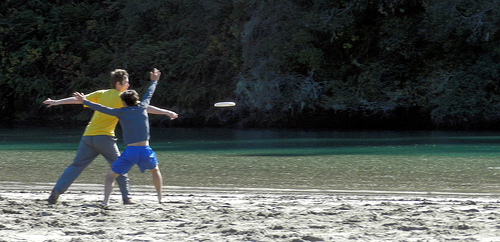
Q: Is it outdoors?
A: Yes, it is outdoors.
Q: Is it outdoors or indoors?
A: It is outdoors.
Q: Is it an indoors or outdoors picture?
A: It is outdoors.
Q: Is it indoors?
A: No, it is outdoors.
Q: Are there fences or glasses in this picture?
A: No, there are no fences or glasses.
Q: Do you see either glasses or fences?
A: No, there are no fences or glasses.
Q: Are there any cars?
A: No, there are no cars.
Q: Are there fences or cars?
A: No, there are no cars or fences.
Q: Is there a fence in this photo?
A: No, there are no fences.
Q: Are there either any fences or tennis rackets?
A: No, there are no fences or tennis rackets.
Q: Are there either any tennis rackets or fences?
A: No, there are no fences or tennis rackets.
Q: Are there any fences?
A: No, there are no fences.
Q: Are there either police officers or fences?
A: No, there are no fences or police officers.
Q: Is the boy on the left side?
A: Yes, the boy is on the left of the image.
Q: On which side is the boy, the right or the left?
A: The boy is on the left of the image.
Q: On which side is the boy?
A: The boy is on the left of the image.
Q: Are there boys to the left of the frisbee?
A: Yes, there is a boy to the left of the frisbee.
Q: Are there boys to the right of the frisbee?
A: No, the boy is to the left of the frisbee.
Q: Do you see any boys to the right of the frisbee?
A: No, the boy is to the left of the frisbee.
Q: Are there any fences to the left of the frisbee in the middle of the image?
A: No, there is a boy to the left of the frisbee.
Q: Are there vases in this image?
A: No, there are no vases.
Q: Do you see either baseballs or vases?
A: No, there are no vases or baseballs.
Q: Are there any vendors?
A: No, there are no vendors.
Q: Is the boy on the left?
A: Yes, the boy is on the left of the image.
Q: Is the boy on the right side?
A: No, the boy is on the left of the image.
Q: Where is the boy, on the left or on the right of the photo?
A: The boy is on the left of the image.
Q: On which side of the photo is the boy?
A: The boy is on the left of the image.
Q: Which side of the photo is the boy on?
A: The boy is on the left of the image.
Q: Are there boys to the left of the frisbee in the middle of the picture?
A: Yes, there is a boy to the left of the frisbee.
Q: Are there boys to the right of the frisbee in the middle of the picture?
A: No, the boy is to the left of the frisbee.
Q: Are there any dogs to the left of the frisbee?
A: No, there is a boy to the left of the frisbee.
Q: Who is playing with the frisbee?
A: The boy is playing with the frisbee.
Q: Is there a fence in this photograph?
A: No, there are no fences.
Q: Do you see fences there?
A: No, there are no fences.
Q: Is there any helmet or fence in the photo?
A: No, there are no fences or helmets.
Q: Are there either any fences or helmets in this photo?
A: No, there are no fences or helmets.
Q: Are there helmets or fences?
A: No, there are no fences or helmets.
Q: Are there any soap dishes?
A: No, there are no soap dishes.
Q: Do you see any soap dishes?
A: No, there are no soap dishes.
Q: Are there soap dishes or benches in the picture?
A: No, there are no soap dishes or benches.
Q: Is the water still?
A: Yes, the water is still.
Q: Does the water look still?
A: Yes, the water is still.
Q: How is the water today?
A: The water is still.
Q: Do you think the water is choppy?
A: No, the water is still.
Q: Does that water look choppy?
A: No, the water is still.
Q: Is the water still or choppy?
A: The water is still.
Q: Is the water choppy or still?
A: The water is still.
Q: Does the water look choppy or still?
A: The water is still.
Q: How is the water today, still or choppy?
A: The water is still.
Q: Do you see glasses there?
A: No, there are no glasses.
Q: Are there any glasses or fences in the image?
A: No, there are no glasses or fences.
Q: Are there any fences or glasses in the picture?
A: No, there are no glasses or fences.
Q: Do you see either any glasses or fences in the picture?
A: No, there are no glasses or fences.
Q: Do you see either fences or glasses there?
A: No, there are no glasses or fences.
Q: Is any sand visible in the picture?
A: Yes, there is sand.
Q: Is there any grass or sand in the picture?
A: Yes, there is sand.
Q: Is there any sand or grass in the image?
A: Yes, there is sand.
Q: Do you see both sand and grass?
A: No, there is sand but no grass.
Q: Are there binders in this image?
A: No, there are no binders.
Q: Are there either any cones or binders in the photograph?
A: No, there are no binders or cones.